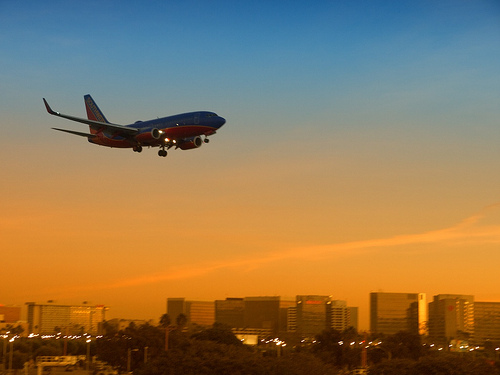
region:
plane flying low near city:
[15, 36, 486, 361]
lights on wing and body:
[37, 100, 182, 150]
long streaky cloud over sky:
[47, 210, 492, 295]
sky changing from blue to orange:
[5, 20, 491, 287]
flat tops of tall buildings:
[17, 286, 493, 321]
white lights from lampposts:
[2, 325, 497, 355]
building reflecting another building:
[365, 286, 427, 336]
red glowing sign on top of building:
[292, 291, 332, 336]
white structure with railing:
[11, 346, 122, 367]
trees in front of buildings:
[88, 307, 493, 372]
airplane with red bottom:
[29, 85, 230, 166]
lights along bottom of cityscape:
[7, 321, 481, 357]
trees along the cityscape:
[97, 317, 258, 364]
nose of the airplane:
[215, 114, 230, 132]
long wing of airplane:
[39, 93, 133, 134]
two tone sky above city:
[6, 13, 493, 292]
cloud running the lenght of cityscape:
[62, 218, 485, 293]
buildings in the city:
[12, 287, 489, 349]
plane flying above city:
[44, 87, 226, 158]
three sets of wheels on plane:
[128, 127, 218, 167]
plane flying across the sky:
[39, 81, 230, 157]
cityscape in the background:
[4, 287, 487, 370]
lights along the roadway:
[10, 321, 498, 358]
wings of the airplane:
[36, 91, 135, 147]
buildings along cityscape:
[17, 284, 491, 341]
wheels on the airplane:
[125, 137, 220, 165]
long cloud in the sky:
[80, 211, 490, 286]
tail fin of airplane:
[76, 90, 114, 132]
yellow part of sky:
[12, 183, 494, 301]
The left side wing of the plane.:
[39, 92, 141, 146]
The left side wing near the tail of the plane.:
[46, 116, 102, 143]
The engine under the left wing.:
[123, 123, 165, 145]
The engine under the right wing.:
[180, 130, 205, 155]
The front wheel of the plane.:
[203, 133, 213, 145]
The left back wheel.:
[134, 141, 140, 153]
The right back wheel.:
[158, 145, 168, 158]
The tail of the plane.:
[76, 90, 103, 137]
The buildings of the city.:
[2, 251, 484, 361]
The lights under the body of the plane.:
[160, 131, 177, 145]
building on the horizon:
[22, 296, 111, 335]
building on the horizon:
[159, 292, 218, 330]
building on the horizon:
[285, 290, 362, 335]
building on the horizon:
[365, 288, 432, 344]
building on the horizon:
[430, 289, 479, 346]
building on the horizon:
[465, 298, 498, 346]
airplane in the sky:
[40, 87, 228, 160]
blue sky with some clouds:
[0, 0, 498, 295]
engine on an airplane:
[131, 125, 165, 145]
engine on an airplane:
[176, 133, 208, 153]